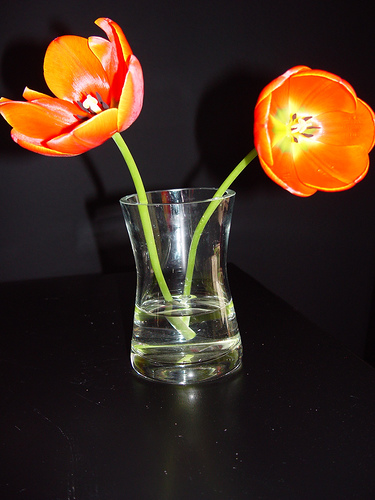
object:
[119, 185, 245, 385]
vase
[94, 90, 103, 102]
stamen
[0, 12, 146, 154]
bloom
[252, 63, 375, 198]
bloom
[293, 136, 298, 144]
stamen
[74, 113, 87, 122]
stamen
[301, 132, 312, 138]
stamen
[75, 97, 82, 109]
stamen